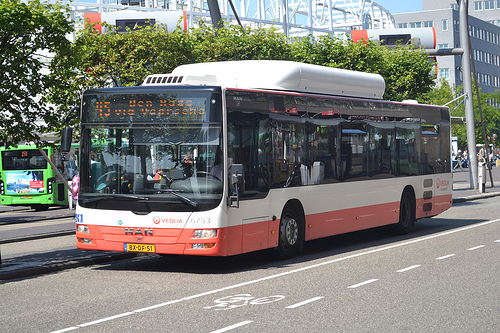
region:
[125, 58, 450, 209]
this is a bus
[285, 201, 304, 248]
this is the wheel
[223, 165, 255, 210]
this is a mirror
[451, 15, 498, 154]
this is a pole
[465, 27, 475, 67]
the pole is white in color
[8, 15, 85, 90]
this is a tree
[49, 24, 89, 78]
the leaves are green in color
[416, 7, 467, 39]
this is a building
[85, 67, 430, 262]
this is a bus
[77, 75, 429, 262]
the bus is long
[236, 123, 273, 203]
this is the window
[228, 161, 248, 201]
this is the side mirror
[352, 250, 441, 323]
this is the road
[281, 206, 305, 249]
this is the wheel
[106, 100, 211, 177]
this is the front screen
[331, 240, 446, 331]
the road is tarmacked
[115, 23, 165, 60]
these are the trees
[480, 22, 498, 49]
this is a building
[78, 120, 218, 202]
windshield on a bus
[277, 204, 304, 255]
front wheel on a bus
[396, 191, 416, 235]
back wheel on a bus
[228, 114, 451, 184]
windows on a bus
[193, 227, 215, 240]
headlight on a bus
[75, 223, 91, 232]
headlight on a bus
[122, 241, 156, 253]
license plate on a bus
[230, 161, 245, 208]
a bus' side view mirror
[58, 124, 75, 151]
a bus' side view mirror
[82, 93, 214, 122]
led sign on a bus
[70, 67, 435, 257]
this is a bus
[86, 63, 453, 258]
the bus is long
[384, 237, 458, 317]
this is the road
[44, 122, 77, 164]
this is the side mirror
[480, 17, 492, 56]
this is a building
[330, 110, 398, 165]
the windows are tinted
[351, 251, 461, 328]
the road is tarmacked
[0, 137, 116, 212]
A large green bus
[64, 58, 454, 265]
A white and orange bus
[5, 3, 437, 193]
the tops of some trees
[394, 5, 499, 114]
A large grey building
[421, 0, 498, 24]
A large grey building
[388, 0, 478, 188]
A large metal pole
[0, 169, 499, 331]
An asphalt road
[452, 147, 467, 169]
a person walking on the street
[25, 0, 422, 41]
a clear blue sky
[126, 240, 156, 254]
a yellow license plate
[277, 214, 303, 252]
the round rubber bus wheel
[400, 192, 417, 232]
the round rubber bus wheel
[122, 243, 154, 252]
the red yellow and black license plate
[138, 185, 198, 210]
the black windshield wiper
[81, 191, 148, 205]
the black windshield wiper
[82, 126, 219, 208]
the broad clear windshield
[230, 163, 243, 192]
the black side mirror of the bus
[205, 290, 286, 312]
the white painted bike on the street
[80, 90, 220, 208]
window on a bus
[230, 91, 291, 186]
window on a bus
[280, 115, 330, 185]
window on a bus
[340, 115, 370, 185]
window on a bus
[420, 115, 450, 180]
window on a bus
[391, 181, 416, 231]
tire on a bus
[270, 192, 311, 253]
tire on a bus